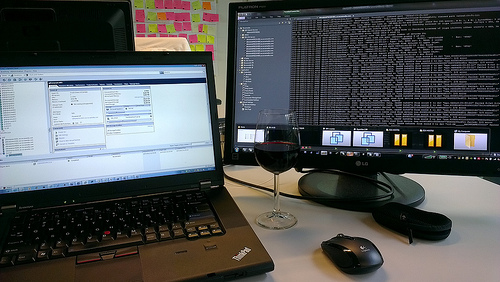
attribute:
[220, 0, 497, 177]
computer screen —   lit ,  computer's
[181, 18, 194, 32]
post note —  pink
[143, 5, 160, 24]
sticky note — yellow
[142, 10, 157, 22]
post it —  yellow,  note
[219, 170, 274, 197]
black cord — long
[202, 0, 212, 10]
note — orange, sticky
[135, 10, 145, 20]
post it — pink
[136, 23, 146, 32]
post it — pink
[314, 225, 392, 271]
mouse — grey, black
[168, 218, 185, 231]
button — black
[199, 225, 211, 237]
button — black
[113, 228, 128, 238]
button — black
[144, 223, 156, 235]
button — black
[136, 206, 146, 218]
button — black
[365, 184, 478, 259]
case — black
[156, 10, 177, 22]
post it —  note,  orange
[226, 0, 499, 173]
monitor — large, computer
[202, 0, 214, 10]
sticky note — orange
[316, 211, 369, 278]
mouse — black, wireless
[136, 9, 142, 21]
sticky note — yellow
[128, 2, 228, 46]
notes — colored 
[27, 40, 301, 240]
laptop — black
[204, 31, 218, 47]
sticky note — pink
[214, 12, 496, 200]
screen — black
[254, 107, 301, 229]
glass — clear, wine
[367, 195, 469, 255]
case — black 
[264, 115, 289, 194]
glass — wine, sitting